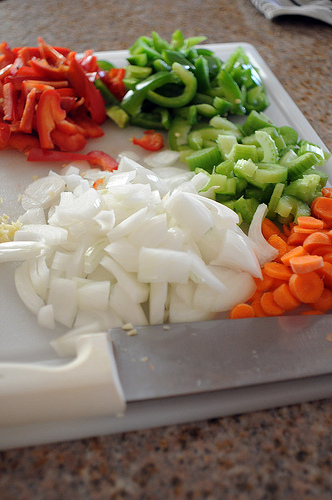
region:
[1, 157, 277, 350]
Onions on a board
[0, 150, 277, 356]
Onions on a cutting board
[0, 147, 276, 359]
White onions on a board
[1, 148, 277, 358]
White onions on a cutting board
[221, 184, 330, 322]
Carrots on a board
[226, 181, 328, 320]
Carrots on a cutting board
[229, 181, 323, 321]
Sliced carrots on a board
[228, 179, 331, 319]
Sliced carrots on a cutting board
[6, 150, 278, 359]
Chopped onions on a board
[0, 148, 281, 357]
Chopped onions on a cutting board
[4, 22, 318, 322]
Platter of raw chopped vegetables.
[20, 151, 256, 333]
Chopped onion on the plate.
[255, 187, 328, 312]
Sliced carrots on the plate.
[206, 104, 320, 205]
Sliced celery on the plate.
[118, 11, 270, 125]
Sliced green peppers on the plate.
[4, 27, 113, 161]
Sliced red peppers on the plate.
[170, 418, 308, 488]
Granite counter top with the plate on top.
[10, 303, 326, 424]
Large knife that was used for chopping.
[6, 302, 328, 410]
The knife has a white handle.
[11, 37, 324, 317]
These vegetables will be used for stir fry.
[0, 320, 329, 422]
Knife with white handle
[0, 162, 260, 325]
Chopped onions on top of cutting board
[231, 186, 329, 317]
Chopped carrots on top of cutting board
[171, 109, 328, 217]
Chopped celery on top of cutting board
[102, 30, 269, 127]
Chopped green peppers on top of cutting board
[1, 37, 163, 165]
Chopped red peppers on top of cutting board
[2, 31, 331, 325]
Chopped vegetables on top of cutting board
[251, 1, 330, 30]
Book in corner of background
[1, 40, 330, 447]
White cutting board on top of table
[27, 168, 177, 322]
a pile of chopped onions on the plate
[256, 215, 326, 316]
the pile of round carrot slices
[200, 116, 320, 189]
the green onions by the carrots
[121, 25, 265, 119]
the green peppers on the cutting board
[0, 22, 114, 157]
a pile of red peppers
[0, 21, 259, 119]
the peepers on the end of the cutting board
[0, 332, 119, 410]
the white handle of the knife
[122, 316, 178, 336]
the crumbs on the blade of the knife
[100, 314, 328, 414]
the balde of the knife on the cutting board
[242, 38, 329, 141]
the corner of the white cutting board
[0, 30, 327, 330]
Chopped veggies for soup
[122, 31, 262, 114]
Chopped green bell peppers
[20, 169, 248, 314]
Chopped White onion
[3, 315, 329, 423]
Tools of the trade a chefs knife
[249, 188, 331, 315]
Chopped orange carrot circles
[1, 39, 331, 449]
Cutting board full of veggies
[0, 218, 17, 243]
Crushed or chopped garlic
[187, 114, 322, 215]
Green sliced celery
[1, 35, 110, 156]
Diced sweet red bell pepper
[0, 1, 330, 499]
Granite looking counter top